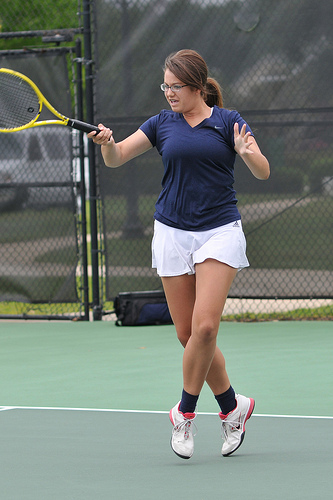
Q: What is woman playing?
A: Tennis.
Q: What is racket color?
A: Yellow.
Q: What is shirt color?
A: Blue.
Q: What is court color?
A: Green.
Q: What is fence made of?
A: Metal.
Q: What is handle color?
A: Black.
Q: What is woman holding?
A: Racket.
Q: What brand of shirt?
A: Nike.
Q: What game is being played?
A: Tennis.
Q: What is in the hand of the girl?
A: Racket.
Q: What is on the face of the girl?
A: Glasses.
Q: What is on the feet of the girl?
A: Sneakers.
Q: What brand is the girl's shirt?
A: Nike.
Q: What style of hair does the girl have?
A: Long hair.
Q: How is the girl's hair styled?
A: Ponytail.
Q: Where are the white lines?
A: On the tennis court.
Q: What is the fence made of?
A: Metal.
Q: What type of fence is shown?
A: Chain link.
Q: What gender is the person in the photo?
A: Female.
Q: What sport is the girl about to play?
A: Tennis.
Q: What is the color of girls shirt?
A: Blue.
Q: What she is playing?
A: Tennis.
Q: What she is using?
A: Tennis bat.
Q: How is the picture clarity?
A: Good.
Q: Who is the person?
A: Female.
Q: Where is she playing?
A: Tennis court.